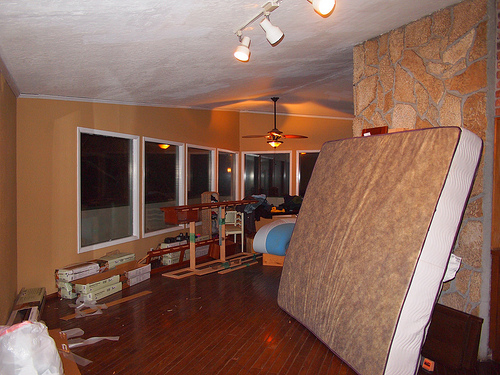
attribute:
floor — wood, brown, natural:
[37, 254, 358, 373]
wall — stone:
[353, 0, 499, 368]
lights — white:
[233, 3, 337, 66]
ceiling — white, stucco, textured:
[0, 2, 473, 119]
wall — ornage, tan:
[1, 58, 354, 322]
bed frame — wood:
[422, 303, 483, 374]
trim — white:
[77, 128, 138, 251]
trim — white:
[140, 136, 185, 237]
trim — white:
[187, 144, 214, 202]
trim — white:
[219, 148, 238, 198]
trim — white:
[243, 150, 291, 202]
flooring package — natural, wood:
[56, 245, 153, 305]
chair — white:
[224, 212, 246, 253]